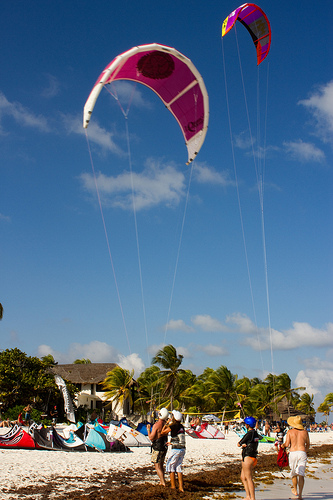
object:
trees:
[101, 343, 317, 423]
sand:
[1, 431, 332, 498]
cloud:
[77, 157, 185, 213]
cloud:
[194, 162, 237, 189]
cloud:
[284, 139, 325, 162]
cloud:
[298, 77, 332, 140]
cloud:
[59, 115, 127, 156]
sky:
[0, 0, 332, 427]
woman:
[237, 416, 260, 498]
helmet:
[244, 416, 256, 428]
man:
[280, 415, 309, 499]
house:
[52, 363, 136, 421]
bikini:
[247, 456, 258, 466]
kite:
[83, 43, 209, 166]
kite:
[220, 3, 272, 67]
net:
[169, 407, 247, 426]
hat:
[287, 416, 305, 430]